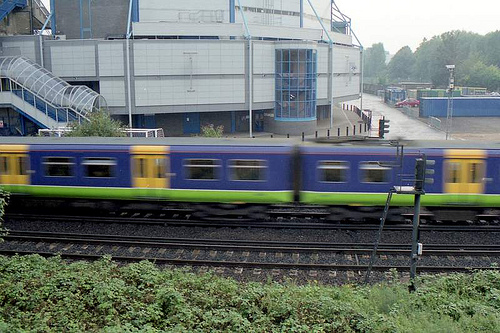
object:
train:
[1, 136, 500, 207]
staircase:
[1, 54, 114, 138]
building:
[0, 0, 372, 145]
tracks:
[0, 231, 199, 266]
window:
[275, 48, 318, 120]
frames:
[275, 100, 318, 121]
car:
[395, 97, 420, 107]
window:
[183, 157, 220, 182]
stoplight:
[413, 154, 435, 188]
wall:
[133, 40, 248, 115]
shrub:
[2, 253, 500, 331]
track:
[206, 239, 499, 271]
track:
[0, 199, 499, 232]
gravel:
[2, 219, 490, 245]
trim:
[107, 102, 258, 116]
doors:
[151, 152, 171, 189]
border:
[2, 183, 499, 212]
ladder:
[365, 187, 396, 285]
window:
[315, 160, 349, 184]